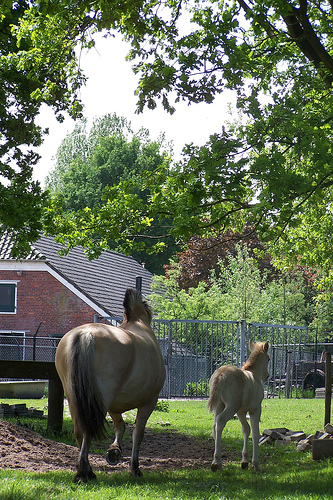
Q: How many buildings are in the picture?
A: One.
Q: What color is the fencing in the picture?
A: Silver.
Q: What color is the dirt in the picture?
A: Light Brown.